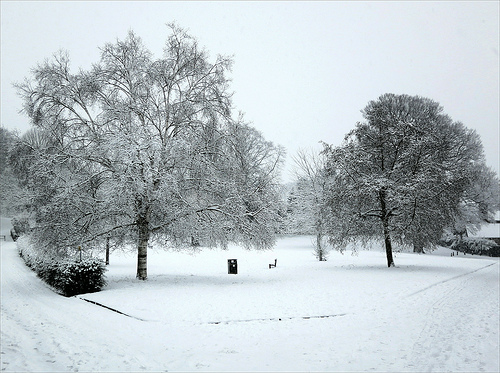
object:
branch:
[357, 200, 425, 271]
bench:
[269, 259, 277, 269]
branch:
[190, 204, 205, 219]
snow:
[207, 290, 477, 358]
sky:
[6, 2, 500, 184]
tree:
[280, 176, 324, 234]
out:
[1, 0, 500, 373]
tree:
[304, 93, 500, 267]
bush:
[16, 240, 109, 297]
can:
[228, 258, 238, 274]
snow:
[14, 299, 380, 360]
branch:
[383, 205, 400, 224]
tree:
[0, 20, 289, 283]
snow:
[16, 27, 281, 242]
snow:
[23, 240, 62, 270]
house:
[460, 222, 500, 245]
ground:
[0, 235, 499, 373]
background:
[2, 0, 499, 257]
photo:
[2, 2, 499, 373]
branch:
[120, 168, 167, 232]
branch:
[68, 208, 95, 222]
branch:
[124, 103, 164, 142]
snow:
[304, 104, 468, 234]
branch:
[146, 205, 265, 234]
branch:
[57, 220, 137, 246]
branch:
[28, 90, 93, 130]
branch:
[64, 90, 84, 107]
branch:
[132, 107, 163, 141]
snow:
[2, 325, 115, 371]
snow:
[34, 256, 105, 297]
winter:
[4, 3, 498, 368]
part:
[192, 210, 199, 219]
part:
[397, 214, 398, 217]